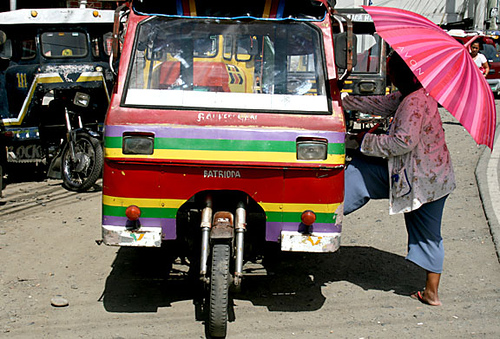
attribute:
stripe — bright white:
[126, 90, 326, 115]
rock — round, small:
[46, 292, 71, 309]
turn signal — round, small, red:
[295, 209, 326, 229]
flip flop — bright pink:
[388, 273, 447, 315]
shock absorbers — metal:
[196, 197, 248, 279]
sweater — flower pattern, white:
[339, 85, 453, 217]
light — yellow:
[90, 7, 102, 17]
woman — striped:
[342, 48, 456, 304]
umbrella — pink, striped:
[367, 3, 499, 139]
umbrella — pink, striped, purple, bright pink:
[365, 4, 496, 149]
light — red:
[125, 207, 142, 222]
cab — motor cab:
[115, 31, 397, 323]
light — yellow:
[117, 128, 160, 163]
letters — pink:
[394, 39, 427, 79]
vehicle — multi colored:
[90, 0, 357, 330]